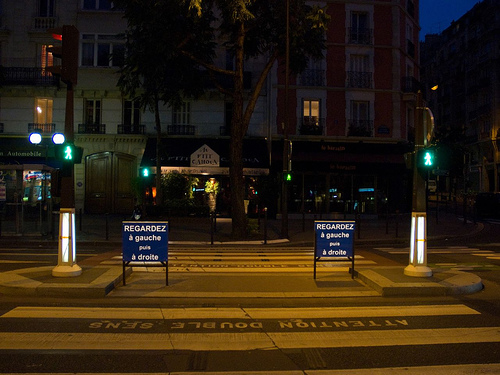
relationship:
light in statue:
[407, 207, 434, 265] [401, 135, 445, 281]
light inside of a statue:
[203, 177, 218, 192] [183, 147, 231, 216]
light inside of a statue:
[202, 177, 216, 192] [184, 142, 220, 202]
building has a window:
[10, 54, 93, 135] [36, 102, 51, 122]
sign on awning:
[194, 149, 217, 166] [184, 165, 231, 176]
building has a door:
[23, 68, 153, 218] [85, 159, 139, 214]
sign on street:
[122, 219, 170, 270] [186, 268, 326, 371]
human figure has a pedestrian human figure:
[423, 150, 435, 167] [423, 150, 435, 167]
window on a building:
[294, 100, 324, 129] [274, 40, 382, 150]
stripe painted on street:
[116, 300, 373, 320] [141, 290, 395, 360]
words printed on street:
[168, 311, 416, 329] [186, 250, 316, 370]